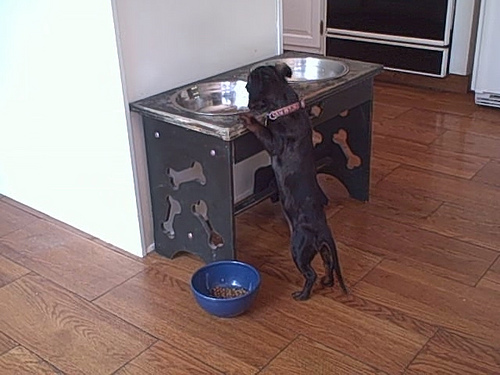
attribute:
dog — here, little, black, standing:
[243, 51, 347, 302]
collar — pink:
[263, 77, 333, 131]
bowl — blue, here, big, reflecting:
[192, 226, 263, 325]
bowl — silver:
[167, 82, 268, 143]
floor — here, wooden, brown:
[41, 218, 157, 312]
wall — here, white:
[45, 42, 116, 243]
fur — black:
[278, 133, 320, 257]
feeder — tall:
[149, 53, 394, 264]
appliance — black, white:
[322, 2, 468, 93]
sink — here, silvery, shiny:
[288, 1, 327, 47]